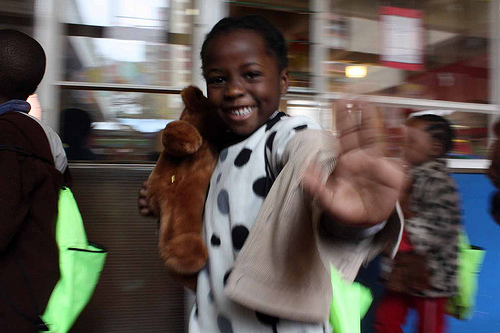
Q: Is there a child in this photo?
A: Yes, there is a child.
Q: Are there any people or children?
A: Yes, there is a child.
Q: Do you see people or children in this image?
A: Yes, there is a child.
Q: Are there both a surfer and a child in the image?
A: No, there is a child but no surfers.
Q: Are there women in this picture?
A: No, there are no women.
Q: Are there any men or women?
A: No, there are no women or men.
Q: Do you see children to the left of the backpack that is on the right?
A: Yes, there is a child to the left of the backpack.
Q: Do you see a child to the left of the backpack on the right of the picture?
A: Yes, there is a child to the left of the backpack.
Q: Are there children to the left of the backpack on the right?
A: Yes, there is a child to the left of the backpack.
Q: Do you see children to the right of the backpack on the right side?
A: No, the child is to the left of the backpack.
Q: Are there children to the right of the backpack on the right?
A: No, the child is to the left of the backpack.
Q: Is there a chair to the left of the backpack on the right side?
A: No, there is a child to the left of the backpack.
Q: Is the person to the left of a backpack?
A: Yes, the kid is to the left of a backpack.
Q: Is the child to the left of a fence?
A: No, the child is to the left of a backpack.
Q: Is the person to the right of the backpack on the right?
A: No, the child is to the left of the backpack.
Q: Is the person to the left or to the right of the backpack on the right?
A: The child is to the left of the backpack.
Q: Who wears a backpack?
A: The kid wears a backpack.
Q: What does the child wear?
A: The child wears a backpack.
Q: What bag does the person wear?
A: The child wears a backpack.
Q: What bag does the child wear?
A: The child wears a backpack.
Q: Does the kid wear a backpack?
A: Yes, the kid wears a backpack.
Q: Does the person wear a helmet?
A: No, the kid wears a backpack.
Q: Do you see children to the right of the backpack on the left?
A: Yes, there is a child to the right of the backpack.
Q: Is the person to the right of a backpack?
A: Yes, the kid is to the right of a backpack.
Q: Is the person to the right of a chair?
A: No, the child is to the right of a backpack.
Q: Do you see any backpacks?
A: Yes, there is a backpack.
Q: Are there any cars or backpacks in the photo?
A: Yes, there is a backpack.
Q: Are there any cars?
A: No, there are no cars.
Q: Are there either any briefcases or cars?
A: No, there are no cars or briefcases.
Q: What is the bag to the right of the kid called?
A: The bag is a backpack.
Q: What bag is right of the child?
A: The bag is a backpack.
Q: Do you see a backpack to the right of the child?
A: Yes, there is a backpack to the right of the child.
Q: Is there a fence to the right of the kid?
A: No, there is a backpack to the right of the kid.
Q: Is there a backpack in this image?
A: Yes, there is a backpack.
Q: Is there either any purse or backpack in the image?
A: Yes, there is a backpack.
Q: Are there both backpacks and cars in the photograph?
A: No, there is a backpack but no cars.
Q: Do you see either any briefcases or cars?
A: No, there are no cars or briefcases.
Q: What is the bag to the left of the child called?
A: The bag is a backpack.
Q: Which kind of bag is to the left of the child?
A: The bag is a backpack.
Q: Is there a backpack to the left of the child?
A: Yes, there is a backpack to the left of the child.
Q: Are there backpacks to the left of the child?
A: Yes, there is a backpack to the left of the child.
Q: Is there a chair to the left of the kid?
A: No, there is a backpack to the left of the kid.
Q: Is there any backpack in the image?
A: Yes, there is a backpack.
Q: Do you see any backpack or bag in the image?
A: Yes, there is a backpack.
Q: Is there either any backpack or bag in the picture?
A: Yes, there is a backpack.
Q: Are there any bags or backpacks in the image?
A: Yes, there is a backpack.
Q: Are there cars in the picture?
A: No, there are no cars.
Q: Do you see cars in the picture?
A: No, there are no cars.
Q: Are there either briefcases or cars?
A: No, there are no cars or briefcases.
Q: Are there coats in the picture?
A: Yes, there is a coat.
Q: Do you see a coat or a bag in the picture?
A: Yes, there is a coat.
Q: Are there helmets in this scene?
A: No, there are no helmets.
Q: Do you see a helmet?
A: No, there are no helmets.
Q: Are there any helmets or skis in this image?
A: No, there are no helmets or skis.